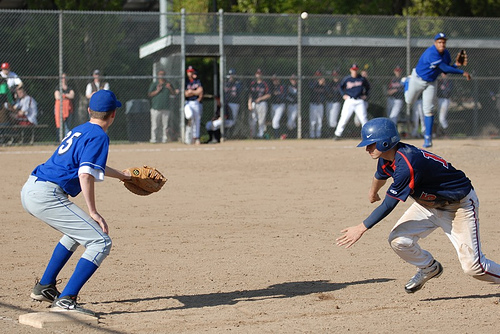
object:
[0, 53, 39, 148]
people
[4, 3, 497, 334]
baseball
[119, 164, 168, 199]
catchers mitt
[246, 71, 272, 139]
kid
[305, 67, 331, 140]
kid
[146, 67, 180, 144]
guy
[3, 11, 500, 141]
fence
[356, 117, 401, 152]
helmet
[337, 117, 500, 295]
kid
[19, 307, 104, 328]
base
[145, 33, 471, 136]
dug out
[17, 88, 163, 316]
kid